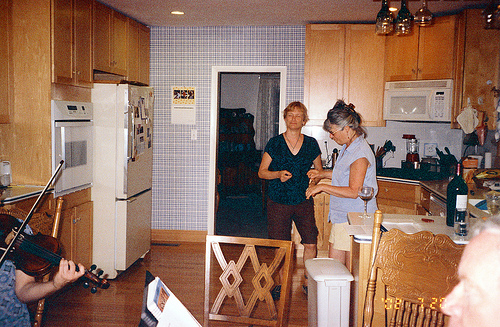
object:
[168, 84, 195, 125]
calendar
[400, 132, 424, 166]
blender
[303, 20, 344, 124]
cabinet door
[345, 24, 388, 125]
cabinet door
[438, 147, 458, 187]
knife block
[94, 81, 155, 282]
fridge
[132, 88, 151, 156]
photos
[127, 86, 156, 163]
notes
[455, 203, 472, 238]
wine glass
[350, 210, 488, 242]
countertop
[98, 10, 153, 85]
cabinets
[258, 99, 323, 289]
woman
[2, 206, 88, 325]
person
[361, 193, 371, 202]
red wine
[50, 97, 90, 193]
oven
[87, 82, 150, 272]
refrigerator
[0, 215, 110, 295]
violin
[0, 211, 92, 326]
child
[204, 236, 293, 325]
chair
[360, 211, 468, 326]
chair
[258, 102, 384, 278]
women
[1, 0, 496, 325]
kitchen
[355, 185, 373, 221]
glass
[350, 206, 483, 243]
table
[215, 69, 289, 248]
door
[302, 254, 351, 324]
trash bin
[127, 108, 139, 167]
handle grip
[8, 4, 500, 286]
wall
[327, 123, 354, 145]
face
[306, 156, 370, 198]
arm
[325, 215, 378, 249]
shorts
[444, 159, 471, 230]
bottle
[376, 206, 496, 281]
counter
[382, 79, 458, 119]
microwave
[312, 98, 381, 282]
woman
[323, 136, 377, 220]
shirt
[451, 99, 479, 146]
pot holders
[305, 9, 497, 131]
cabinet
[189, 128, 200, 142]
light switch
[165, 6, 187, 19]
recessed light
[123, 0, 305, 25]
ceiling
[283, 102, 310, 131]
head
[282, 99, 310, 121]
hair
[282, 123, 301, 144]
neck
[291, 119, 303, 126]
mouth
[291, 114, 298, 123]
nose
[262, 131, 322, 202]
shirt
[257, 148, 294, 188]
right arm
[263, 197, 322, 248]
shorts